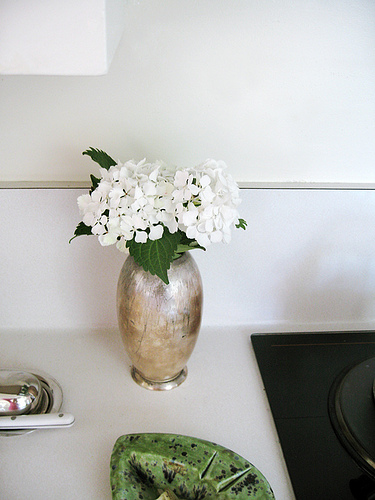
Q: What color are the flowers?
A: WHite.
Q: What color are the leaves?
A: Green.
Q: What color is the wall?
A: White.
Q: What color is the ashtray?
A: Green.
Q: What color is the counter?
A: White.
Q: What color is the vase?
A: Brown.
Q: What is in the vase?
A: Flowers.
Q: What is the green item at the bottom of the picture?
A: Ashtray.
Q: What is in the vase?
A: White flowers and green leaves.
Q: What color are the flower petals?
A: White.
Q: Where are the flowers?
A: Silver vase.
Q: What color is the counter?
A: White.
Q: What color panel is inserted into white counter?
A: Black.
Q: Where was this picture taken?
A: Kitchen counter.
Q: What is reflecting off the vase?
A: Light.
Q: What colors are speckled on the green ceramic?
A: Black and brown.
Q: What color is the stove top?
A: Black.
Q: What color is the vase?
A: Silver.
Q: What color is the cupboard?
A: White.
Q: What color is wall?
A: White.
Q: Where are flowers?
A: In vase.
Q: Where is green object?
A: On counter.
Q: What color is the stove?
A: Black.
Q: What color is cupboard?
A: White.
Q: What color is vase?
A: Brown.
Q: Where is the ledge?
A: Behind flowers.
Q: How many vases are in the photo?
A: One.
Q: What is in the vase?
A: Flowers.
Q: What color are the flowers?
A: White.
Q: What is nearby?
A: A chrome desk lamp base.